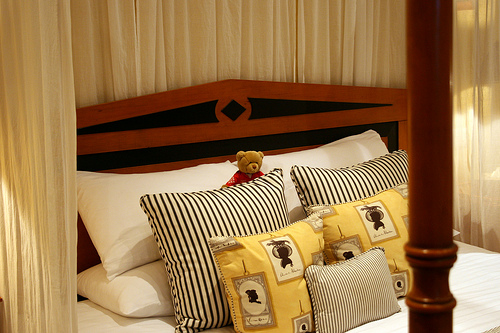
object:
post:
[403, 1, 458, 333]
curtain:
[0, 0, 500, 333]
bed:
[75, 78, 499, 332]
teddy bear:
[221, 151, 265, 189]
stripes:
[139, 168, 291, 333]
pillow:
[140, 151, 413, 333]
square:
[220, 100, 246, 122]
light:
[451, 88, 499, 237]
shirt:
[226, 170, 264, 187]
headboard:
[76, 78, 408, 174]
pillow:
[303, 245, 401, 332]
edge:
[63, 1, 79, 332]